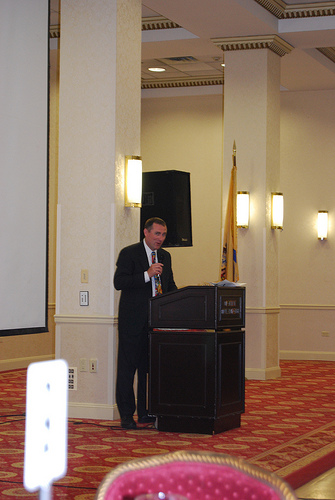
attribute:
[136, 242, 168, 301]
shirt — white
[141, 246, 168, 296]
tie — floral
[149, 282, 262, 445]
stand — black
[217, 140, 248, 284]
flag — yellow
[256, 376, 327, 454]
carpet — red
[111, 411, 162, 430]
shoe — black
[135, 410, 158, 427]
shoe — black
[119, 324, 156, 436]
pants — black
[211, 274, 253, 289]
paper — white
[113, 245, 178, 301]
jacket — black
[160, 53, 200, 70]
vent — heating, air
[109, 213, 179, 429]
man — speaking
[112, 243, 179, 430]
suit — black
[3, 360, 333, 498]
carpeting — red, gold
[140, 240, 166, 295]
dress shirt — white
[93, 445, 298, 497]
chair — gold, red, patterned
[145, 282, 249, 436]
podium — solid black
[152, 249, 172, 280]
microphone — black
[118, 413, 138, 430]
shoe — black, shiny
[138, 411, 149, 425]
shoe — black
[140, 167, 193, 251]
object — black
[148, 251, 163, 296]
tie — colorful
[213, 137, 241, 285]
flag — yellow, colored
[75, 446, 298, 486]
chair — red